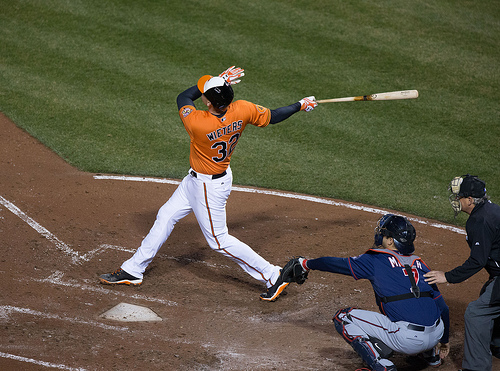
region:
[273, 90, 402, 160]
Man swinging baseball bat.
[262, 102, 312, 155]
Man has on black long sleeved shirt.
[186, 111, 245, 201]
Man is wearing orange jersey.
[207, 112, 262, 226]
Batter is number 32.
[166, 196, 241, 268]
Man is wearing white pants.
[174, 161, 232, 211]
Man is wearing black belt.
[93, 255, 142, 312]
Man has on black, white, and orange shoes.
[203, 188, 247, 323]
Orange strip down man's pants.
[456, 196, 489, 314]
Umpire is wearing black shirt.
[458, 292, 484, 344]
Umpire has on gray pants.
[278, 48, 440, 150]
hand holding baseball bat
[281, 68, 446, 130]
right hand holding baseball bat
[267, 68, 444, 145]
gloved hand holding baseball bat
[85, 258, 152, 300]
right foot planted on ground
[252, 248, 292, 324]
left foot planted on ground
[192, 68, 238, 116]
person wearing ball cap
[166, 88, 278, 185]
ball player wearing orange shirt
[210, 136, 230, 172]
number "3" showing on jersey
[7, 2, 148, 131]
patch of green grass field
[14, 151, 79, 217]
patch of brown ball field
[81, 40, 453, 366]
baseball players at home base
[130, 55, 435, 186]
batter with both arms to one side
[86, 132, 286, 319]
one leg far in front of the other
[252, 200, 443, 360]
catcher with left arm extended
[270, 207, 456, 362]
baseball player crouched on dirt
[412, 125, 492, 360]
umpire leaning on catcher's back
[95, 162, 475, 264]
white line in front of grass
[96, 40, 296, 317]
player wearing black, orange and white uniform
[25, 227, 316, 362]
white lines wearing away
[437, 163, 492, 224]
protective headwear being worn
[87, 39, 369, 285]
base ballplayer wearing a ball cap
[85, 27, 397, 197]
baseball wearing a orange jersery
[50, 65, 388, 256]
baseball player wearing a long sleeve black shirt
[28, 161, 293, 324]
baseball player wearing white athlete pants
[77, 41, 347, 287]
baseball wearing a pair of tennis shoes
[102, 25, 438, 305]
baseball player swinging a baseball bat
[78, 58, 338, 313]
baseball player wearing batting gloves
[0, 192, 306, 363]
baseball player standing in the batters box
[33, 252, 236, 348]
white home plate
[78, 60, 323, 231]
the baseball player is number 33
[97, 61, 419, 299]
Baseball batter swinging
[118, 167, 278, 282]
White pants with stripe on baseball batter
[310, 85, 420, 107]
Brown bat swung by baseball batter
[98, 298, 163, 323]
White home plate on a baseball field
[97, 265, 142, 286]
Orange, white, and black shoe of baseball batter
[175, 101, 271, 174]
Orange jersey with black lettering on baseball batter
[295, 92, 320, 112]
Orange and white batting glove worn by baseball player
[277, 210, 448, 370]
Catcher squatting in baseball game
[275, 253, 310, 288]
Black mitt of baseball catcher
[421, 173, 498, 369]
Home plate umpire of baseball game